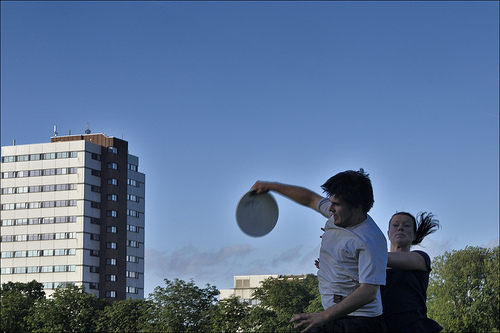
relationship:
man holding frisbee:
[232, 164, 395, 331] [233, 188, 282, 239]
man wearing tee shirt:
[232, 164, 395, 331] [314, 191, 389, 318]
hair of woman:
[387, 208, 443, 247] [311, 209, 449, 331]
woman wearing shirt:
[311, 209, 449, 331] [362, 249, 447, 332]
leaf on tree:
[15, 296, 20, 299] [0, 277, 48, 332]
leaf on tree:
[8, 297, 11, 300] [0, 277, 48, 332]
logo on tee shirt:
[331, 292, 346, 306] [314, 191, 389, 318]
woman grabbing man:
[311, 209, 449, 331] [232, 164, 395, 331]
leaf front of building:
[15, 296, 20, 299] [0, 120, 151, 302]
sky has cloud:
[2, 2, 499, 301] [223, 244, 247, 257]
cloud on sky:
[223, 244, 247, 257] [2, 2, 499, 301]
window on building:
[64, 217, 73, 223] [0, 120, 151, 302]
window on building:
[63, 249, 70, 254] [0, 120, 151, 302]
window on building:
[64, 200, 74, 208] [0, 120, 151, 302]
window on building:
[105, 240, 119, 253] [0, 120, 151, 302]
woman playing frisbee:
[311, 209, 449, 331] [233, 188, 282, 239]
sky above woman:
[2, 2, 499, 301] [311, 209, 449, 331]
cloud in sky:
[223, 244, 247, 257] [2, 2, 499, 301]